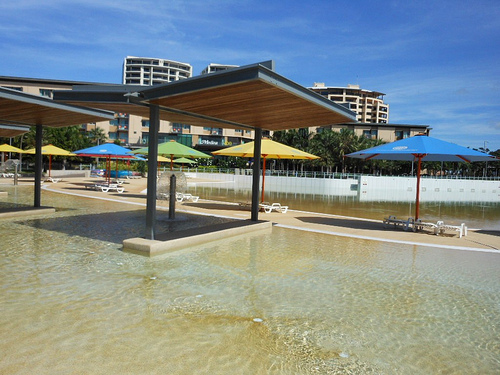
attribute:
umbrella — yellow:
[211, 131, 323, 216]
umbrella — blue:
[343, 132, 497, 172]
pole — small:
[168, 174, 177, 220]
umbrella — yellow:
[211, 136, 318, 160]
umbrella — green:
[134, 134, 236, 174]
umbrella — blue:
[347, 132, 488, 224]